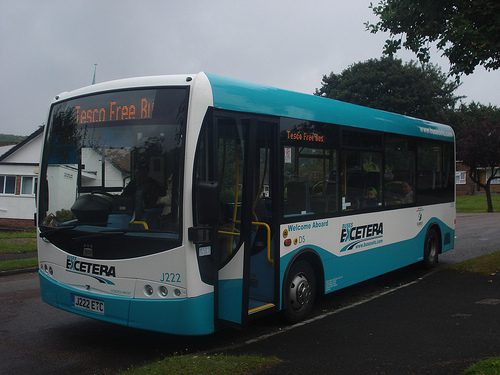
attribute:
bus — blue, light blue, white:
[33, 69, 459, 341]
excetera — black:
[62, 255, 118, 281]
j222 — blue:
[156, 271, 183, 286]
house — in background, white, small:
[1, 110, 47, 232]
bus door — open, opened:
[206, 102, 282, 332]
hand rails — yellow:
[220, 139, 275, 268]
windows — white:
[2, 170, 39, 198]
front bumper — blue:
[31, 267, 216, 339]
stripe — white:
[276, 201, 458, 257]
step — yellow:
[248, 300, 277, 317]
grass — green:
[2, 193, 500, 374]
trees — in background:
[312, 1, 500, 213]